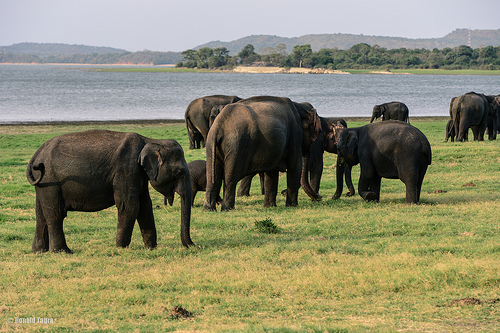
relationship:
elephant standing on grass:
[26, 128, 198, 252] [2, 119, 498, 331]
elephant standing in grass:
[197, 95, 325, 214] [2, 119, 498, 331]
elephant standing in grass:
[186, 95, 247, 149] [2, 119, 498, 331]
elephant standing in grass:
[330, 121, 430, 200] [2, 119, 498, 331]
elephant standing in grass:
[449, 93, 492, 143] [2, 119, 498, 331]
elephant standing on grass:
[371, 102, 411, 124] [2, 119, 498, 331]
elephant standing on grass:
[185, 160, 213, 206] [2, 119, 498, 331]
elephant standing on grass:
[235, 116, 343, 201] [2, 119, 498, 331]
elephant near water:
[371, 102, 411, 124] [0, 62, 499, 124]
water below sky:
[0, 62, 499, 124] [1, 1, 498, 50]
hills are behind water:
[1, 25, 499, 64] [0, 62, 499, 124]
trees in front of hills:
[178, 43, 499, 73] [1, 25, 499, 64]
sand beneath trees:
[233, 65, 349, 73] [178, 43, 499, 73]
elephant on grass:
[26, 128, 198, 252] [2, 119, 498, 331]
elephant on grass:
[197, 95, 325, 214] [2, 119, 498, 331]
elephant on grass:
[185, 160, 213, 206] [2, 119, 498, 331]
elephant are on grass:
[23, 128, 203, 256] [2, 119, 498, 331]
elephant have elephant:
[23, 128, 203, 256] [185, 158, 210, 209]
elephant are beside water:
[23, 128, 203, 256] [0, 62, 499, 124]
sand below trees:
[233, 65, 349, 73] [178, 43, 499, 73]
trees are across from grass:
[178, 43, 499, 73] [2, 119, 498, 331]